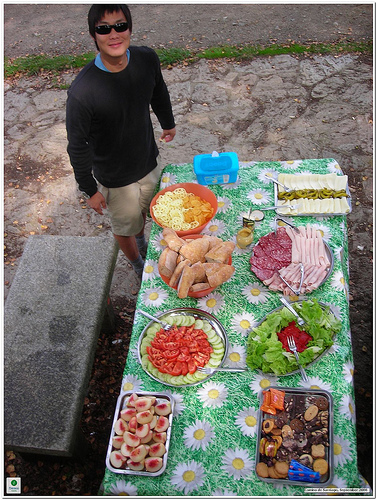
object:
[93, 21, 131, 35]
sunglasses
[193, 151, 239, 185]
box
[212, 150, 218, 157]
wipes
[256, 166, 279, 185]
flower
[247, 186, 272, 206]
flower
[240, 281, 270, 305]
flower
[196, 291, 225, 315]
flower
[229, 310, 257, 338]
flower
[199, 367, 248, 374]
fork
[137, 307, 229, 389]
plate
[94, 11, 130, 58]
face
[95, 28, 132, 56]
smile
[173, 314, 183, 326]
cucumber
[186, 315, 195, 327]
cucumber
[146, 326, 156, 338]
cucumber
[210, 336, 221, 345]
cucumber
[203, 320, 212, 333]
cucumber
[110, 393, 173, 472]
peaches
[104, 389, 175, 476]
tray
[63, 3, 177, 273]
cookies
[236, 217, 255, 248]
mustard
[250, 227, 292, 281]
meat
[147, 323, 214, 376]
tomatoe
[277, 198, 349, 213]
cheeses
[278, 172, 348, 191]
cheeses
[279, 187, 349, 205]
pickles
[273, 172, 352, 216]
tray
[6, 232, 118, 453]
stone bench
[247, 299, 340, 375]
lettuce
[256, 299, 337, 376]
plate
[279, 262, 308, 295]
tongs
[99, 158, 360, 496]
table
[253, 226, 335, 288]
tray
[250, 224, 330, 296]
deli meats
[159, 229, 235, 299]
bread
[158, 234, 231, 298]
bowl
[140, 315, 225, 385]
cucumbers